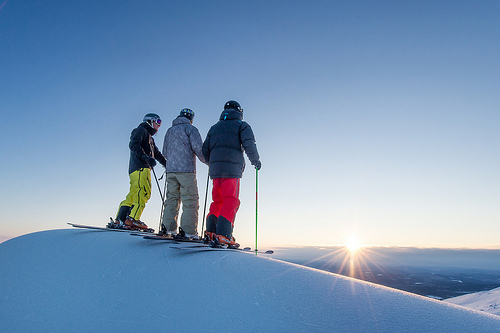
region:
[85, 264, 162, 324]
white snow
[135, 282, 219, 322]
white snow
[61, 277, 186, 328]
white snow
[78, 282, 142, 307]
white snow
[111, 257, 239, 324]
white snow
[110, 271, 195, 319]
white snow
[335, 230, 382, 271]
Sun shining on horizon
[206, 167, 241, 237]
Skier with red pants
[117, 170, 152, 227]
Man wearing yellow pants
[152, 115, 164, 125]
Goggles on a man's eyes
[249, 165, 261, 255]
Green ski pole in the snow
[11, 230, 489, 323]
Top of a snowy hill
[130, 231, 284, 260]
Skis on top of a slope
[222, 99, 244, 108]
Hat on a man's head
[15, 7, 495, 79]
Cloudless blue sky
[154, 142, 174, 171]
Man pointing with this left hand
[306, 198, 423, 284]
bright sun shine rays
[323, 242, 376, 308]
bright sun shine rays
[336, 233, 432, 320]
bright sun shine rays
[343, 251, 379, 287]
bright sun shine rays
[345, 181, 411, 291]
bright sun shine rays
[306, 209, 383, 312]
bright sun shine rays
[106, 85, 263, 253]
The skiers on the top of the mountain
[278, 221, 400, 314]
The sun on the horizon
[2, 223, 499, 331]
The hill the skiers are on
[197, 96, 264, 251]
The person with red pants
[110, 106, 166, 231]
The person with yellow pants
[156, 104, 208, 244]
The person in the tan pants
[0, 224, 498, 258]
The horizon line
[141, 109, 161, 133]
The helmet of the person on the left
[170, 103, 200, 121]
The helmet of the person in the middle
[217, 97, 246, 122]
The helmet of the person on the right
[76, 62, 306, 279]
skiers on hill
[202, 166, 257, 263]
snowboard pants on skier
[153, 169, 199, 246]
snowboard pants on skier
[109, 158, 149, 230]
snowboard pants on skier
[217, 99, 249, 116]
helment on skier's head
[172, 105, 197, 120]
helment on skier's head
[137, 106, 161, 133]
helment on skier's head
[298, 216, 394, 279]
sun shining in distance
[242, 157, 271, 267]
bright ski poles in hand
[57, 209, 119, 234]
skis on top of hill